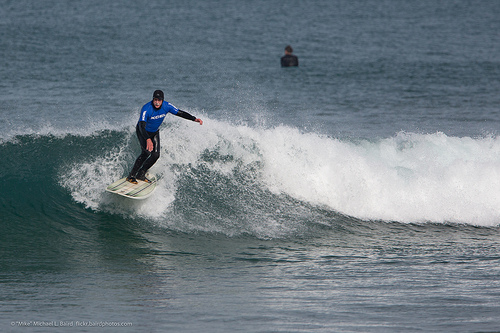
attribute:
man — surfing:
[125, 90, 202, 184]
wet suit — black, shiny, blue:
[126, 101, 194, 179]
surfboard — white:
[104, 174, 162, 200]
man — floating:
[277, 43, 300, 68]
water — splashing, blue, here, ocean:
[1, 0, 497, 328]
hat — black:
[153, 89, 164, 98]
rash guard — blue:
[138, 100, 177, 132]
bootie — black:
[125, 175, 137, 185]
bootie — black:
[137, 174, 151, 182]